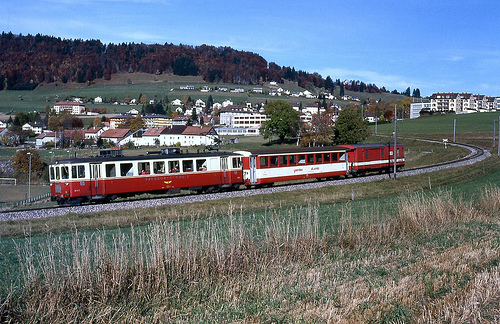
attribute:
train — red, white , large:
[49, 143, 385, 198]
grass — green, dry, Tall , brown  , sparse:
[83, 227, 442, 312]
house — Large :
[123, 118, 223, 139]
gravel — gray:
[24, 203, 203, 222]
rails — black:
[443, 125, 478, 179]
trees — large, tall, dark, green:
[25, 34, 268, 76]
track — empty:
[413, 125, 462, 189]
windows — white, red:
[55, 156, 225, 174]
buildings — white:
[424, 75, 499, 119]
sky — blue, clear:
[218, 8, 493, 87]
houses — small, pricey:
[34, 91, 154, 153]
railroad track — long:
[11, 134, 494, 244]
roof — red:
[416, 87, 493, 103]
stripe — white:
[348, 149, 420, 173]